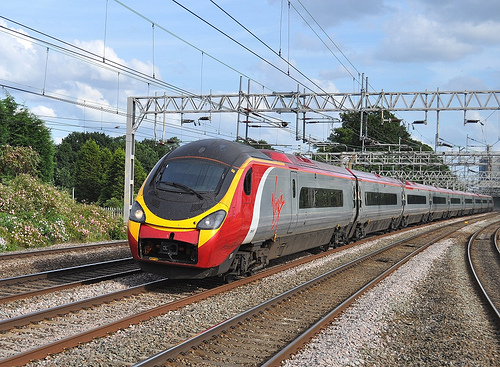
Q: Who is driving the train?
A: The Conductor.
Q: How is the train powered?
A: Electrically.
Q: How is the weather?
A: Nice.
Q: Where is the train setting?
A: On the tracks.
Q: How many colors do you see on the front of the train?
A: Two, yellow and red.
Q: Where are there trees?
A: On the left side of the train.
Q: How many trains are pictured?
A: One.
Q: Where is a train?
A: On train tracks.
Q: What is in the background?
A: Trees.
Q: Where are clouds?
A: In the sky.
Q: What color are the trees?
A: Green.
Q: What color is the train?
A: Gray, red and yellow.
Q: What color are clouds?
A: White.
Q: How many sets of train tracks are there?
A: Four.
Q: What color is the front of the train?
A: Red, yellow and black.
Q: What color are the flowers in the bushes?
A: Pink.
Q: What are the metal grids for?
A: Holding power lines.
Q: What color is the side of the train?
A: Grey.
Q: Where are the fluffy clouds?
A: In the sky.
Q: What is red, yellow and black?
A: The front of the train.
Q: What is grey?
A: The back of the train.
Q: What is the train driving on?
A: Tracks.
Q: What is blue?
A: Sky.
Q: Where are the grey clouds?
A: In the sky.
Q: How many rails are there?
A: 4.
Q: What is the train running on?
A: Railway tracks.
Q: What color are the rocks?
A: Grey.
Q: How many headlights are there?
A: 2.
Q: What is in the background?
A: Trees.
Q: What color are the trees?
A: Green.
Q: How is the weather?
A: Cloudy.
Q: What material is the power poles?
A: Metal.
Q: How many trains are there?
A: 1.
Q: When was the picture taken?
A: During the day.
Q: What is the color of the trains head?
A: Black.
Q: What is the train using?
A: Rail.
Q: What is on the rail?
A: Stones.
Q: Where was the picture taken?
A: At the train tracks.